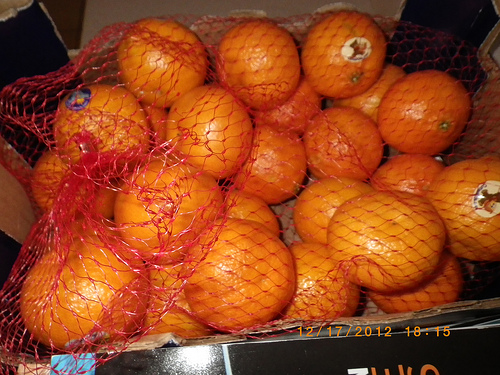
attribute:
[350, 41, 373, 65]
sticker — white, blue, brown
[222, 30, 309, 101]
orange — end, light, round, center, yellow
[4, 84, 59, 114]
bag — red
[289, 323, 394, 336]
date — picture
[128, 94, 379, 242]
oranges — pile, piled, small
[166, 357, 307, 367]
box — bottom, torn, black, brown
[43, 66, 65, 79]
netting — red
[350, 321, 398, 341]
2012 — date